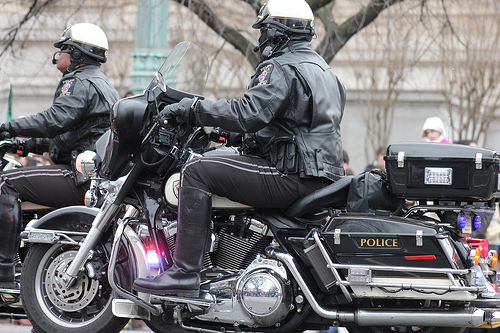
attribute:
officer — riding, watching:
[132, 0, 346, 297]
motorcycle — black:
[20, 42, 500, 332]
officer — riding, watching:
[0, 21, 121, 289]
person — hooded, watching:
[421, 115, 451, 143]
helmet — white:
[250, 0, 315, 36]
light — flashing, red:
[146, 250, 164, 266]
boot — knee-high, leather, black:
[135, 186, 213, 298]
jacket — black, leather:
[192, 36, 346, 180]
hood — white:
[419, 116, 446, 133]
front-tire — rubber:
[20, 243, 131, 332]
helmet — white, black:
[55, 22, 108, 62]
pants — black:
[181, 154, 335, 210]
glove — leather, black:
[157, 100, 181, 128]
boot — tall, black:
[0, 194, 21, 282]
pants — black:
[0, 165, 94, 209]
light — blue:
[458, 210, 467, 231]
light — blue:
[473, 211, 481, 231]